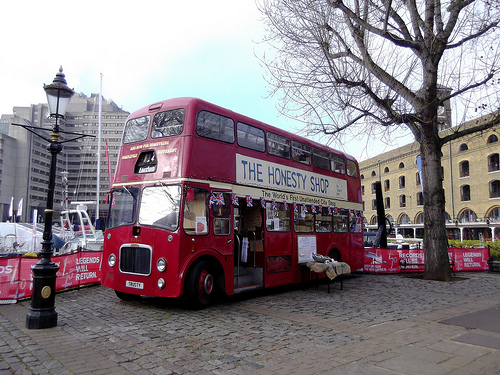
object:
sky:
[0, 0, 500, 160]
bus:
[100, 96, 365, 311]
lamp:
[43, 85, 76, 118]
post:
[10, 123, 96, 330]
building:
[358, 108, 500, 243]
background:
[0, 0, 499, 239]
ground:
[0, 274, 500, 375]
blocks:
[436, 306, 500, 350]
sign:
[236, 152, 349, 202]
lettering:
[241, 160, 330, 194]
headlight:
[156, 257, 167, 273]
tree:
[248, 0, 500, 280]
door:
[234, 197, 266, 295]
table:
[298, 260, 351, 293]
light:
[157, 278, 165, 290]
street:
[0, 271, 500, 375]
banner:
[234, 152, 349, 202]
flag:
[208, 192, 225, 209]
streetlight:
[11, 64, 97, 329]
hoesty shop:
[267, 166, 329, 193]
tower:
[414, 82, 454, 133]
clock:
[437, 106, 445, 116]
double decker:
[100, 96, 364, 310]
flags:
[246, 194, 254, 207]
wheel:
[185, 259, 216, 310]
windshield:
[139, 185, 182, 232]